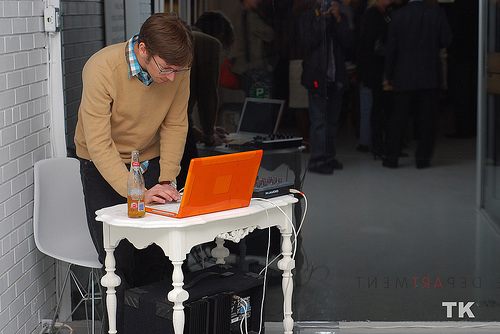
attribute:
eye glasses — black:
[149, 53, 196, 80]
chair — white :
[30, 162, 87, 279]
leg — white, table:
[272, 214, 299, 331]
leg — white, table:
[161, 244, 193, 332]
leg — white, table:
[96, 232, 124, 329]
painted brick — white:
[0, 0, 125, 332]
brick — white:
[15, 54, 36, 70]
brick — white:
[10, 84, 41, 108]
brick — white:
[19, 266, 48, 283]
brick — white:
[26, 272, 54, 309]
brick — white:
[5, 4, 47, 29]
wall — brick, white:
[1, 2, 63, 332]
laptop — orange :
[107, 119, 275, 246]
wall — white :
[3, 25, 63, 157]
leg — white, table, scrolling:
[164, 253, 194, 332]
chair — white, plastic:
[19, 147, 113, 325]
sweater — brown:
[72, 34, 192, 198]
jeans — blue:
[308, 73, 339, 170]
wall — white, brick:
[11, 80, 41, 105]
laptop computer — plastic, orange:
[145, 148, 263, 218]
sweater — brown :
[96, 52, 201, 178]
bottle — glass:
[128, 147, 148, 217]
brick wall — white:
[1, 3, 107, 332]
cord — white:
[250, 197, 272, 331]